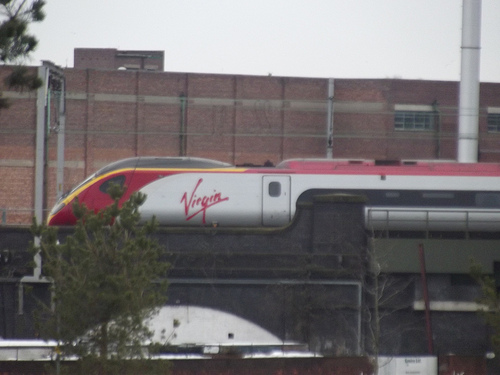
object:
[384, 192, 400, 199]
window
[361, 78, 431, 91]
edge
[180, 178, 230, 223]
logo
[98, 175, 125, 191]
window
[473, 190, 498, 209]
window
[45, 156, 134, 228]
nose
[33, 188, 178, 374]
tree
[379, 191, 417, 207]
windows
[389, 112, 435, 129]
window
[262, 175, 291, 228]
door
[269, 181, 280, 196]
window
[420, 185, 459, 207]
window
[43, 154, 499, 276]
train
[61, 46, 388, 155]
building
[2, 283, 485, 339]
train tracks